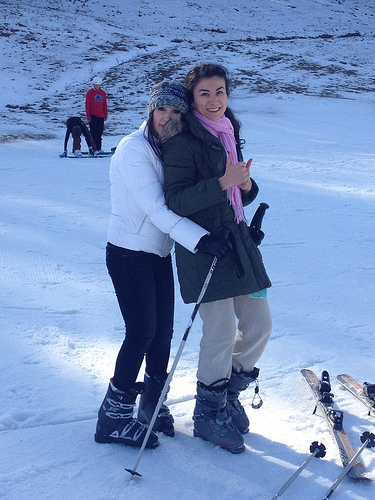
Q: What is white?
A: Snow.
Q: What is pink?
A: Scarf.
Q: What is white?
A: Woman's jacket.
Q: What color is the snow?
A: White.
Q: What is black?
A: Woman's gloves.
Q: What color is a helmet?
A: White.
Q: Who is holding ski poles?
A: Woman on left.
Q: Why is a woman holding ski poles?
A: To ski.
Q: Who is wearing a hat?
A: Woman on left.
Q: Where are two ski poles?
A: On the ground.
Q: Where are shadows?
A: On the snow.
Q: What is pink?
A: Scarf.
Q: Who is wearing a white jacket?
A: Woman on left.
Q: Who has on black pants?
A: Woman on left.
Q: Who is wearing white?
A: Woman at the back.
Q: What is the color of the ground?
A: White.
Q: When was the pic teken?
A: During the day.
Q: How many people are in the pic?
A: 4.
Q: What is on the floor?
A: Shadow.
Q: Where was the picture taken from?
A: Mountain.